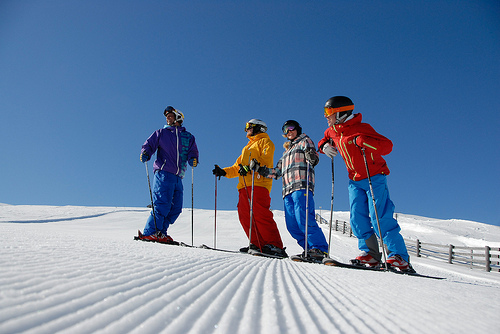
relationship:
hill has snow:
[75, 262, 262, 315] [35, 207, 94, 248]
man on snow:
[132, 102, 201, 244] [35, 207, 94, 248]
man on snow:
[212, 119, 288, 260] [35, 207, 94, 248]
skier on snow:
[274, 107, 331, 265] [35, 207, 94, 248]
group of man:
[133, 89, 426, 272] [260, 119, 328, 262]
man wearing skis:
[132, 102, 201, 244] [133, 232, 190, 251]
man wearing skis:
[217, 108, 285, 262] [218, 242, 295, 263]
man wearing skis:
[275, 116, 326, 262] [287, 253, 326, 267]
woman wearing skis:
[321, 99, 414, 257] [339, 264, 424, 286]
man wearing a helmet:
[139, 102, 187, 241] [155, 105, 193, 128]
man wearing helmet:
[275, 116, 326, 262] [284, 121, 301, 138]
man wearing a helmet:
[217, 108, 285, 262] [243, 116, 271, 142]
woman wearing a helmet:
[321, 99, 414, 257] [324, 95, 357, 124]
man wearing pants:
[139, 102, 187, 241] [135, 166, 189, 239]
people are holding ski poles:
[133, 89, 426, 272] [184, 166, 197, 250]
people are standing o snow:
[133, 89, 426, 272] [35, 207, 94, 248]